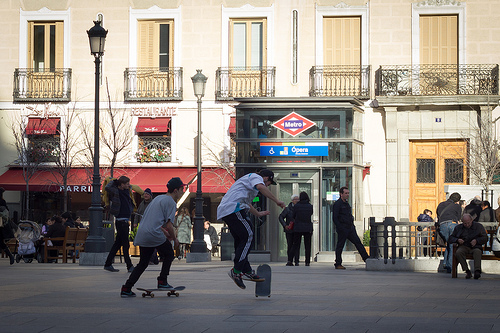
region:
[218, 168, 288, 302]
a skateboarder performing a trick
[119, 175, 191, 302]
a young man running on his skateboard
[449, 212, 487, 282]
a man sitting on a bench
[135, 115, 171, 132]
red canopy on a window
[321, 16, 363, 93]
closed shutters on a window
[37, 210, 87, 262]
people sitting on a wooden bench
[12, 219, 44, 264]
a baby stroller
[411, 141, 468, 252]
a large wooden door on the front of a building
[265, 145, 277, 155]
an handicap sign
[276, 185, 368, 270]
three people standing in a public place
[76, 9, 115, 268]
The streetlamp is off.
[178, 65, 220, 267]
The streetlamp is off.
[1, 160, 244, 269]
The awning is red.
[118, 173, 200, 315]
The boy is riding a skateboard.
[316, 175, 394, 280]
The man is standing.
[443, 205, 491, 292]
The man is sitting.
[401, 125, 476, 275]
The doors are wood.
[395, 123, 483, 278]
The doors have windows.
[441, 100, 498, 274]
The tree is bare.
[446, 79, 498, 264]
The tree is leafless.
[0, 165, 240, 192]
red awning with white word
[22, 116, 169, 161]
two window with awnings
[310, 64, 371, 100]
balcony on face of building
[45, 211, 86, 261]
people sitting on bench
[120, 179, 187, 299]
boy on top of skateboard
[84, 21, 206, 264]
two lights on poles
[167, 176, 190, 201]
hat on boy's head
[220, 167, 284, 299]
boy jumping up in the air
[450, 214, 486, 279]
man sitting on bench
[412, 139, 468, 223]
two doors with windows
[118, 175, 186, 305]
Young man on skateboard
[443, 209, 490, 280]
Man sitting on a bench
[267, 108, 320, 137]
Red and white metro sign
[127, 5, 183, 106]
Window on the front of a building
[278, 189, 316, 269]
Two people talking to each other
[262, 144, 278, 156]
Blue and white handicap sign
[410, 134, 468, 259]
Wooden front door of a building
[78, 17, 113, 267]
Street lamp with black pole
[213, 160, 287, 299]
Man doing a trick on a skateboard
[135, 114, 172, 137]
Red awning above window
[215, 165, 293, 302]
A skateboarder flipping his skateboard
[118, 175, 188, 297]
A skateboarder riding his skateboard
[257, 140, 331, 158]
A handicapped sign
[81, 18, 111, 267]
An unlit lampost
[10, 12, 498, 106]
A row of balconies in a building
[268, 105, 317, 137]
A Metro sign at the entrance to a building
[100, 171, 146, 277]
A man carrying something on his shoulder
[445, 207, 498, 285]
A man sitting on bench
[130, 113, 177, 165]
A window with a flower box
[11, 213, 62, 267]
A woman sitting next to a baby carriage